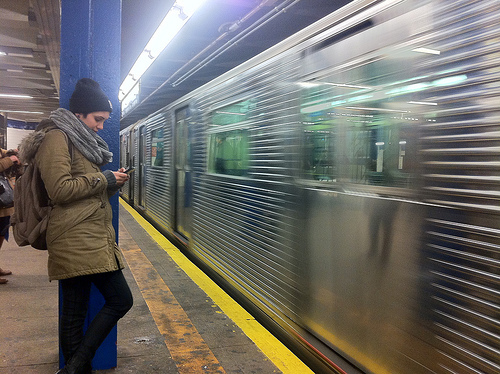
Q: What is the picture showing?
A: It is showing a station.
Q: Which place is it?
A: It is a station.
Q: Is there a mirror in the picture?
A: No, there are no mirrors.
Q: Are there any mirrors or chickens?
A: No, there are no mirrors or chickens.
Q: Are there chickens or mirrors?
A: No, there are no mirrors or chickens.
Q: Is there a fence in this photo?
A: No, there are no fences.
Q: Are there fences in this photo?
A: No, there are no fences.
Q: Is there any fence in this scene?
A: No, there are no fences.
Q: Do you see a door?
A: Yes, there is a door.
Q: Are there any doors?
A: Yes, there is a door.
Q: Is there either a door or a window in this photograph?
A: Yes, there is a door.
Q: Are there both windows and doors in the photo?
A: Yes, there are both a door and a window.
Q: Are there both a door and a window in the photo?
A: Yes, there are both a door and a window.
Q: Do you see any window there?
A: Yes, there is a window.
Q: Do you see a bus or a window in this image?
A: Yes, there is a window.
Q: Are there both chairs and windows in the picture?
A: No, there is a window but no chairs.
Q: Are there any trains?
A: Yes, there is a train.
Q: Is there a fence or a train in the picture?
A: Yes, there is a train.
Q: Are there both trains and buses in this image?
A: No, there is a train but no buses.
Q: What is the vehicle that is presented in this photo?
A: The vehicle is a train.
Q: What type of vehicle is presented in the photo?
A: The vehicle is a train.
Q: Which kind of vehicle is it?
A: The vehicle is a train.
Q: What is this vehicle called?
A: This is a train.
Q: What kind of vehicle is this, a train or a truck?
A: This is a train.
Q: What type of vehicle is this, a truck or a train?
A: This is a train.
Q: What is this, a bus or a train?
A: This is a train.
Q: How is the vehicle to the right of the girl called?
A: The vehicle is a train.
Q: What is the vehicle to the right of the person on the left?
A: The vehicle is a train.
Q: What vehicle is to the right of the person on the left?
A: The vehicle is a train.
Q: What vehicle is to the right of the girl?
A: The vehicle is a train.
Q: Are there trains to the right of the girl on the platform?
A: Yes, there is a train to the right of the girl.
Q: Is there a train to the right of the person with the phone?
A: Yes, there is a train to the right of the girl.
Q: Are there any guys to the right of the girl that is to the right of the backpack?
A: No, there is a train to the right of the girl.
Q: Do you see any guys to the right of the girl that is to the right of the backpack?
A: No, there is a train to the right of the girl.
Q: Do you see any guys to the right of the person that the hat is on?
A: No, there is a train to the right of the girl.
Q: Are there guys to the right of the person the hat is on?
A: No, there is a train to the right of the girl.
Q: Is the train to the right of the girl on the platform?
A: Yes, the train is to the right of the girl.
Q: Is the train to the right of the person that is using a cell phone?
A: Yes, the train is to the right of the girl.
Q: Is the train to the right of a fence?
A: No, the train is to the right of the girl.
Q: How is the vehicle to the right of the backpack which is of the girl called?
A: The vehicle is a train.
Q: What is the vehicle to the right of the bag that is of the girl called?
A: The vehicle is a train.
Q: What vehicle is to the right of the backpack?
A: The vehicle is a train.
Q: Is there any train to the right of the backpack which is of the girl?
A: Yes, there is a train to the right of the backpack.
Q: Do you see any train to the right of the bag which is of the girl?
A: Yes, there is a train to the right of the backpack.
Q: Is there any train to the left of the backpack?
A: No, the train is to the right of the backpack.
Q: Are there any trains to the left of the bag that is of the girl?
A: No, the train is to the right of the backpack.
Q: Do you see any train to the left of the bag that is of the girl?
A: No, the train is to the right of the backpack.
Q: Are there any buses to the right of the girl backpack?
A: No, there is a train to the right of the backpack.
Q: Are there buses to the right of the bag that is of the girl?
A: No, there is a train to the right of the backpack.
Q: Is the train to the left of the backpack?
A: No, the train is to the right of the backpack.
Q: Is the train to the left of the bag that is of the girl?
A: No, the train is to the right of the backpack.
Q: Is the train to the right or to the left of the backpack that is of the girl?
A: The train is to the right of the backpack.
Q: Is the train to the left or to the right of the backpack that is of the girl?
A: The train is to the right of the backpack.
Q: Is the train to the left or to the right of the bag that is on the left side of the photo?
A: The train is to the right of the backpack.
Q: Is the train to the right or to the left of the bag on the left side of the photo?
A: The train is to the right of the backpack.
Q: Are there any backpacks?
A: Yes, there is a backpack.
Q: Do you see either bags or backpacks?
A: Yes, there is a backpack.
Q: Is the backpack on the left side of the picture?
A: Yes, the backpack is on the left of the image.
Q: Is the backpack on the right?
A: No, the backpack is on the left of the image.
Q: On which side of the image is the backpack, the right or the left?
A: The backpack is on the left of the image.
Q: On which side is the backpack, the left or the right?
A: The backpack is on the left of the image.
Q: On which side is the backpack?
A: The backpack is on the left of the image.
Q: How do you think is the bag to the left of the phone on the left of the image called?
A: The bag is a backpack.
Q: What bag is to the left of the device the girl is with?
A: The bag is a backpack.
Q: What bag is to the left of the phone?
A: The bag is a backpack.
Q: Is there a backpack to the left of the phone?
A: Yes, there is a backpack to the left of the phone.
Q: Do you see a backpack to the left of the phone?
A: Yes, there is a backpack to the left of the phone.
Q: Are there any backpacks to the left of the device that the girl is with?
A: Yes, there is a backpack to the left of the phone.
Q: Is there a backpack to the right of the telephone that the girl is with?
A: No, the backpack is to the left of the phone.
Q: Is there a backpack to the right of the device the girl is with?
A: No, the backpack is to the left of the phone.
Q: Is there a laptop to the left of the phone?
A: No, there is a backpack to the left of the phone.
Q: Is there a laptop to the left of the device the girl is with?
A: No, there is a backpack to the left of the phone.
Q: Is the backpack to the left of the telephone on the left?
A: Yes, the backpack is to the left of the telephone.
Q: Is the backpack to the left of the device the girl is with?
A: Yes, the backpack is to the left of the telephone.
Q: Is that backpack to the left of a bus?
A: No, the backpack is to the left of the telephone.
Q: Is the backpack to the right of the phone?
A: No, the backpack is to the left of the phone.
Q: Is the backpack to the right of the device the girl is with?
A: No, the backpack is to the left of the phone.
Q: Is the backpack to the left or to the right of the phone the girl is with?
A: The backpack is to the left of the telephone.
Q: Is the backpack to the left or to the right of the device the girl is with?
A: The backpack is to the left of the telephone.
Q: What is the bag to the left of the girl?
A: The bag is a backpack.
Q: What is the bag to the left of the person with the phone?
A: The bag is a backpack.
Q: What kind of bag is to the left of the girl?
A: The bag is a backpack.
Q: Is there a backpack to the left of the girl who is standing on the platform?
A: Yes, there is a backpack to the left of the girl.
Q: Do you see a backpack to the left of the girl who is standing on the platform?
A: Yes, there is a backpack to the left of the girl.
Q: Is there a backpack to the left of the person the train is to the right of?
A: Yes, there is a backpack to the left of the girl.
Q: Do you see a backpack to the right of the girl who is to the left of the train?
A: No, the backpack is to the left of the girl.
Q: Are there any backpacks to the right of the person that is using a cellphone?
A: No, the backpack is to the left of the girl.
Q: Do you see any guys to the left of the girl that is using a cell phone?
A: No, there is a backpack to the left of the girl.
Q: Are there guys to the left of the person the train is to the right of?
A: No, there is a backpack to the left of the girl.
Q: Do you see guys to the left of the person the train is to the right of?
A: No, there is a backpack to the left of the girl.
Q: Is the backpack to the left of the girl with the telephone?
A: Yes, the backpack is to the left of the girl.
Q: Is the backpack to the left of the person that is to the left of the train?
A: Yes, the backpack is to the left of the girl.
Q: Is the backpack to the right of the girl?
A: No, the backpack is to the left of the girl.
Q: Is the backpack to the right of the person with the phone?
A: No, the backpack is to the left of the girl.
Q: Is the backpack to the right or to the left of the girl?
A: The backpack is to the left of the girl.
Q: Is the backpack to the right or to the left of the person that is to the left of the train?
A: The backpack is to the left of the girl.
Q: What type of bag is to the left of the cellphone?
A: The bag is a backpack.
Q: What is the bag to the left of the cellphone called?
A: The bag is a backpack.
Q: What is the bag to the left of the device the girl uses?
A: The bag is a backpack.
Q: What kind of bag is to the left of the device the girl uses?
A: The bag is a backpack.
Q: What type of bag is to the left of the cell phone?
A: The bag is a backpack.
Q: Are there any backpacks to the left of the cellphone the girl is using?
A: Yes, there is a backpack to the left of the mobile phone.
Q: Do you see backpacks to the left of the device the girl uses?
A: Yes, there is a backpack to the left of the mobile phone.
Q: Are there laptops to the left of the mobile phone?
A: No, there is a backpack to the left of the mobile phone.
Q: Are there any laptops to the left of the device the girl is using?
A: No, there is a backpack to the left of the mobile phone.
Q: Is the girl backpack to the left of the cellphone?
A: Yes, the backpack is to the left of the cellphone.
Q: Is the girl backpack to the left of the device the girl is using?
A: Yes, the backpack is to the left of the cellphone.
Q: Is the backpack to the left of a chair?
A: No, the backpack is to the left of the cellphone.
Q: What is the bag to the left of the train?
A: The bag is a backpack.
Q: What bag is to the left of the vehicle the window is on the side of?
A: The bag is a backpack.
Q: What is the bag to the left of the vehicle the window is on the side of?
A: The bag is a backpack.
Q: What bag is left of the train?
A: The bag is a backpack.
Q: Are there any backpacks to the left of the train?
A: Yes, there is a backpack to the left of the train.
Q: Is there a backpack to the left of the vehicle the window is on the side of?
A: Yes, there is a backpack to the left of the train.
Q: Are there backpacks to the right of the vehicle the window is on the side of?
A: No, the backpack is to the left of the train.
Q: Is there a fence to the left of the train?
A: No, there is a backpack to the left of the train.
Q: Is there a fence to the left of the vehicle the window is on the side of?
A: No, there is a backpack to the left of the train.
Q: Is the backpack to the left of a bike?
A: No, the backpack is to the left of the train.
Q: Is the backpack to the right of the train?
A: No, the backpack is to the left of the train.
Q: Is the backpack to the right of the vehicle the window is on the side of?
A: No, the backpack is to the left of the train.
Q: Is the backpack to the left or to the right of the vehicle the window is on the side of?
A: The backpack is to the left of the train.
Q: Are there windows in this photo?
A: Yes, there is a window.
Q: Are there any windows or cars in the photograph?
A: Yes, there is a window.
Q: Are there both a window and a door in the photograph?
A: Yes, there are both a window and a door.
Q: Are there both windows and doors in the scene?
A: Yes, there are both a window and a door.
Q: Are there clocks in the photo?
A: No, there are no clocks.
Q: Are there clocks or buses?
A: No, there are no clocks or buses.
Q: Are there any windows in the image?
A: Yes, there is a window.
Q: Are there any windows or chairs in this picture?
A: Yes, there is a window.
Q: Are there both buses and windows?
A: No, there is a window but no buses.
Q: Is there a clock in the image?
A: No, there are no clocks.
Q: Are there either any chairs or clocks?
A: No, there are no clocks or chairs.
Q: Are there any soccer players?
A: No, there are no soccer players.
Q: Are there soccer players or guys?
A: No, there are no soccer players or guys.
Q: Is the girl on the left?
A: Yes, the girl is on the left of the image.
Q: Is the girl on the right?
A: No, the girl is on the left of the image.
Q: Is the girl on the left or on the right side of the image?
A: The girl is on the left of the image.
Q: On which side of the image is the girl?
A: The girl is on the left of the image.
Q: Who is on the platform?
A: The girl is on the platform.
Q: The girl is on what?
A: The girl is on the platform.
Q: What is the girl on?
A: The girl is on the platform.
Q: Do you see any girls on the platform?
A: Yes, there is a girl on the platform.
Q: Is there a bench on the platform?
A: No, there is a girl on the platform.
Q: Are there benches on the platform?
A: No, there is a girl on the platform.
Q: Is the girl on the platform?
A: Yes, the girl is on the platform.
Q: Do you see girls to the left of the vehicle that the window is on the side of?
A: Yes, there is a girl to the left of the train.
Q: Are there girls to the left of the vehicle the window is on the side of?
A: Yes, there is a girl to the left of the train.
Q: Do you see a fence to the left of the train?
A: No, there is a girl to the left of the train.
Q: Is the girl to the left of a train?
A: Yes, the girl is to the left of a train.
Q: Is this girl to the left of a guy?
A: No, the girl is to the left of a train.